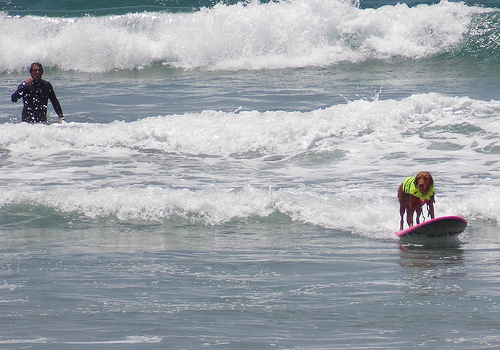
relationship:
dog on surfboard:
[394, 171, 440, 222] [400, 212, 472, 241]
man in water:
[8, 53, 68, 125] [3, 5, 499, 345]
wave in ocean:
[6, 6, 499, 74] [6, 8, 499, 239]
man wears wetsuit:
[8, 53, 68, 125] [25, 95, 52, 115]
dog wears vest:
[394, 171, 440, 222] [400, 177, 432, 196]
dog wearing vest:
[394, 171, 440, 222] [400, 177, 432, 196]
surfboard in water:
[400, 212, 472, 241] [3, 5, 499, 345]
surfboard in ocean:
[400, 212, 472, 241] [6, 8, 499, 239]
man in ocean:
[8, 53, 68, 125] [6, 8, 499, 239]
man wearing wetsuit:
[8, 53, 68, 125] [25, 95, 52, 115]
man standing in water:
[8, 53, 68, 125] [3, 5, 499, 345]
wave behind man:
[6, 6, 499, 74] [8, 53, 68, 125]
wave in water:
[6, 6, 499, 74] [3, 5, 499, 345]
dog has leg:
[394, 171, 440, 222] [400, 204, 406, 228]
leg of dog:
[400, 204, 406, 228] [394, 171, 440, 222]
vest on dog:
[400, 177, 432, 196] [394, 171, 440, 222]